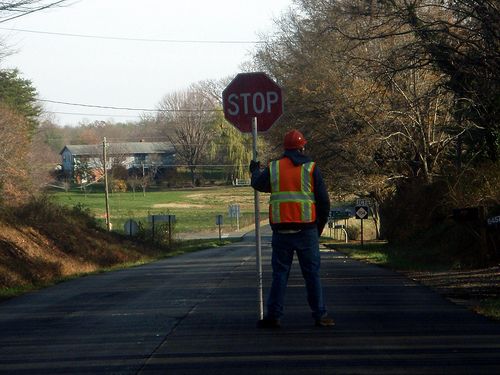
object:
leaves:
[5, 80, 30, 114]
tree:
[0, 0, 78, 62]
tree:
[153, 84, 221, 183]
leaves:
[319, 60, 355, 93]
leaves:
[291, 4, 482, 59]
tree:
[87, 137, 152, 195]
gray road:
[1, 227, 498, 373]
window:
[79, 155, 88, 166]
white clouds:
[75, 30, 195, 104]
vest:
[268, 156, 316, 224]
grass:
[50, 187, 250, 226]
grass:
[343, 238, 388, 262]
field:
[64, 180, 256, 228]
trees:
[0, 64, 61, 204]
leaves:
[331, 129, 416, 185]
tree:
[197, 77, 249, 184]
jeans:
[265, 227, 329, 320]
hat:
[282, 129, 308, 149]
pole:
[250, 116, 264, 321]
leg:
[257, 233, 294, 328]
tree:
[253, 0, 498, 250]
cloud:
[0, 4, 328, 126]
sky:
[0, 0, 306, 130]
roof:
[60, 138, 178, 156]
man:
[248, 129, 336, 327]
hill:
[0, 201, 165, 298]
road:
[0, 221, 498, 374]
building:
[59, 138, 179, 181]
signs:
[123, 218, 143, 236]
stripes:
[268, 156, 315, 224]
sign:
[221, 71, 285, 133]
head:
[282, 130, 307, 154]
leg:
[295, 234, 337, 326]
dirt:
[148, 187, 270, 213]